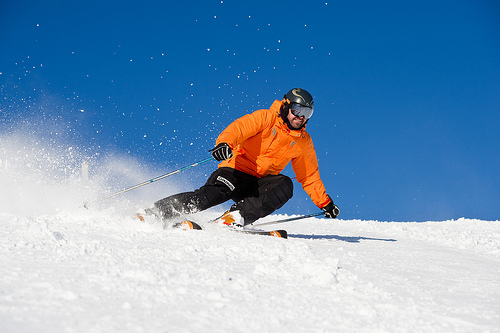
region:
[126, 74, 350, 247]
skier is going down hill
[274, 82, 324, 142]
skier wears a helmet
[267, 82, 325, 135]
black goggles on face of skier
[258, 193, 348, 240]
a pole on left hand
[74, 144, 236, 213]
a pole on right hand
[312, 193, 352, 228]
left hand with glove holding a snow pole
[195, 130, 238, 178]
right hand with glove holding a snow pole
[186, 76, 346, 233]
man wearing a winter coat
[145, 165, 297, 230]
black pants are long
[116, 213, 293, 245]
skis are color black, orange and white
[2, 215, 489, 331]
snow on the ground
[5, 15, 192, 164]
snow particles in the air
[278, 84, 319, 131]
helmet on man's head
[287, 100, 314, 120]
ski goggles on man's face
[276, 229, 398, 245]
shadow on the snow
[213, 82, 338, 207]
bright orange jacket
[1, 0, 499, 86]
dark blue sky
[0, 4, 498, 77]
no clouds in sky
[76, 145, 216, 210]
ski pole in man's hand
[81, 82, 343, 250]
man skiing downhill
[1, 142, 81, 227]
Snow dust kicked up by skier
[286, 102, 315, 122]
Black ski goggles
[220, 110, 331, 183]
Neon orange ski jacket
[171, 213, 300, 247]
Black and orange skis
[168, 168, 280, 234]
Black ski pants with white logo area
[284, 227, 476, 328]
White snow pack on ski trail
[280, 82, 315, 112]
Black ski helmut with yellow line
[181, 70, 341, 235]
Man skiing in snow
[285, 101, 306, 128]
Brown mustache and beard on man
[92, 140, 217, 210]
Silver and blue ski pole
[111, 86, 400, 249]
Man snow sking down hill.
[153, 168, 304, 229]
Man dressed in black pants.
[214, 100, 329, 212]
Man dressed in orange jacket with hood.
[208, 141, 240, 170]
Man wearing black glove on hand.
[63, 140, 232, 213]
Man holding ski pole in hand.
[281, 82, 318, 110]
Man wearing black safety helmet.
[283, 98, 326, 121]
Man wearing goggles over eyes.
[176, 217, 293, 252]
Tip of snow skis attached to man's feet.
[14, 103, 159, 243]
White snow flying up in air.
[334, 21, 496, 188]
Clear blue sky over snow covered hill.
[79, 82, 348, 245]
the man is skiing on the snow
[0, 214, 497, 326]
this is snow on the ground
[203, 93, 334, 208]
the man is wearing an orange coat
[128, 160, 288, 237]
the man is wearing black pants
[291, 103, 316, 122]
the man is wearing goggles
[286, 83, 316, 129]
the man is wearing an helmet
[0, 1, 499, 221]
the sky is cloudless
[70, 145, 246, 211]
this is a skiing pole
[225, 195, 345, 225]
this is a skiing pole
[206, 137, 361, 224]
the man has gloves on